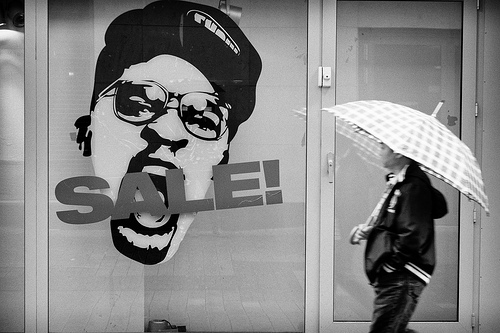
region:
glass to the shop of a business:
[220, 239, 280, 324]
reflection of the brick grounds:
[200, 261, 267, 318]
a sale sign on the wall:
[56, 158, 284, 226]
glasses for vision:
[109, 78, 233, 140]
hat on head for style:
[86, 1, 261, 126]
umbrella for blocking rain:
[328, 90, 495, 216]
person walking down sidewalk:
[361, 144, 441, 331]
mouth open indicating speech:
[126, 160, 175, 228]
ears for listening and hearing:
[71, 126, 99, 153]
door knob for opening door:
[324, 155, 340, 186]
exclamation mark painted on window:
[258, 152, 289, 210]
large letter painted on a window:
[205, 156, 270, 216]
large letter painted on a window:
[160, 159, 217, 221]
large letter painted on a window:
[106, 165, 169, 227]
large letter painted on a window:
[47, 170, 117, 228]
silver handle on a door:
[322, 151, 337, 190]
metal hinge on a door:
[467, 205, 479, 225]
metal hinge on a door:
[471, 100, 479, 118]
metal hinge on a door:
[474, 0, 483, 7]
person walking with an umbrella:
[300, 82, 498, 332]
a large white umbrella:
[368, 73, 483, 190]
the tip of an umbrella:
[435, 85, 449, 132]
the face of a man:
[368, 133, 405, 165]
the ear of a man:
[392, 149, 400, 164]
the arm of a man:
[387, 191, 425, 253]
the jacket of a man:
[374, 183, 449, 280]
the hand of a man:
[345, 215, 380, 246]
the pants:
[364, 268, 431, 326]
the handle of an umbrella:
[351, 216, 362, 256]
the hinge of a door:
[308, 46, 339, 100]